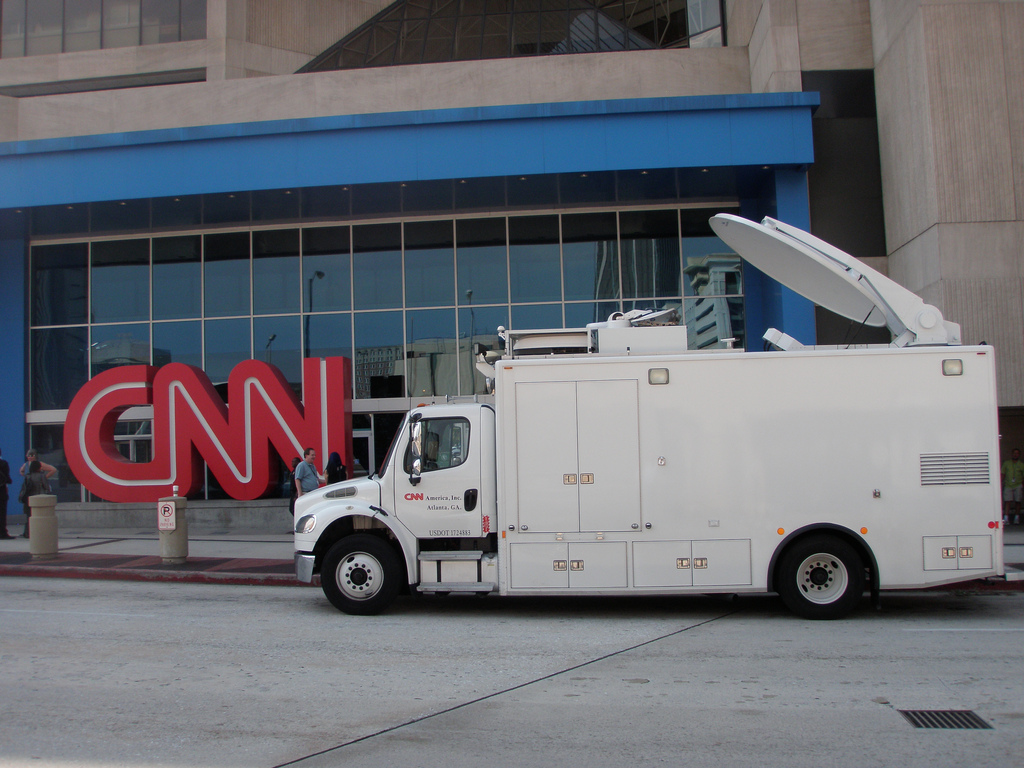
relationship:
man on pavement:
[286, 436, 325, 503] [3, 519, 282, 567]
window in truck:
[398, 411, 478, 487] [273, 182, 993, 608]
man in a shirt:
[286, 437, 325, 504] [288, 467, 317, 496]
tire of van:
[770, 534, 874, 615] [286, 191, 993, 617]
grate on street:
[889, 696, 993, 735] [11, 549, 990, 742]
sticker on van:
[394, 487, 485, 516] [286, 191, 993, 617]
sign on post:
[147, 493, 180, 537] [152, 487, 191, 550]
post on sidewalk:
[145, 484, 200, 551] [5, 513, 287, 574]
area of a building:
[14, 104, 810, 502] [13, 22, 994, 524]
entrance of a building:
[2, 168, 817, 487] [13, 22, 994, 524]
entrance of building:
[18, 96, 822, 490] [13, 22, 994, 524]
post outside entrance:
[145, 484, 200, 551] [18, 96, 822, 490]